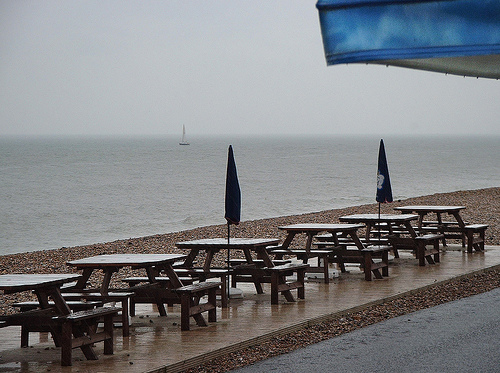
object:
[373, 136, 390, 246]
umbrella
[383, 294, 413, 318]
gravel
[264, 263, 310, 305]
bench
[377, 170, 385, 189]
logo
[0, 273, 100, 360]
table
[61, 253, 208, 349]
table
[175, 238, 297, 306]
table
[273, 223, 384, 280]
table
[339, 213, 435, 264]
table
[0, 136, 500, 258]
water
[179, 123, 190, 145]
boat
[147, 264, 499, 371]
aggregate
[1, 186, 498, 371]
raised area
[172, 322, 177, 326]
pinecones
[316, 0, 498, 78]
fabric canopy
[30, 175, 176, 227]
ripples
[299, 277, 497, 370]
street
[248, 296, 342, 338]
wet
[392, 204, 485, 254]
table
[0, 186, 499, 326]
beach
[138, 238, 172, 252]
gravel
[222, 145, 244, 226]
umbrella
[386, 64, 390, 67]
droplets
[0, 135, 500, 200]
ocean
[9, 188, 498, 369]
surface